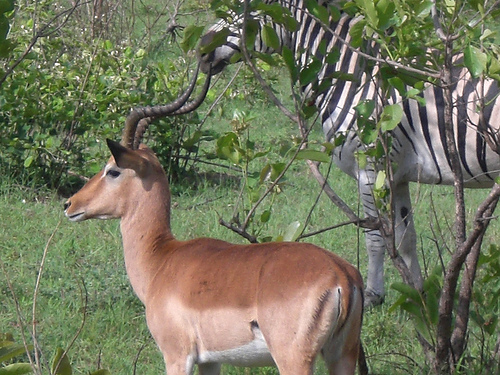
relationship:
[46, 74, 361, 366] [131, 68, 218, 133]
gazelle has horns